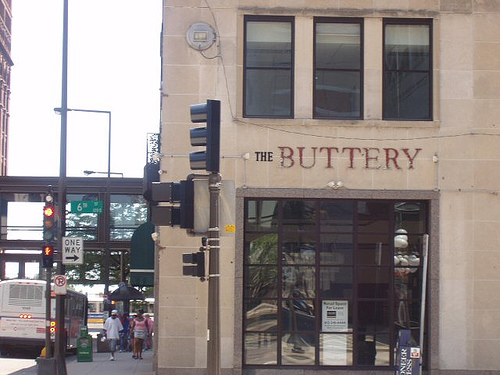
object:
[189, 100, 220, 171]
lamp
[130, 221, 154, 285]
awning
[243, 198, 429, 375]
door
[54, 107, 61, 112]
grey lamps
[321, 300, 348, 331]
paper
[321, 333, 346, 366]
paper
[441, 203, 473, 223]
tan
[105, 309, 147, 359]
couple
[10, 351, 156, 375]
sidewalk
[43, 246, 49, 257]
hand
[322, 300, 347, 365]
papers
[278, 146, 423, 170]
big letters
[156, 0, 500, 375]
building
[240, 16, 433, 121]
brown horses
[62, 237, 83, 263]
sign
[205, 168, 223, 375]
pole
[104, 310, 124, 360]
pedestrian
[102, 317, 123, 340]
white top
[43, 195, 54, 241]
traffic light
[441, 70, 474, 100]
tan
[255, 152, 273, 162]
lettering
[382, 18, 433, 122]
window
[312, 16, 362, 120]
window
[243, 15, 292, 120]
window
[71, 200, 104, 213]
6th street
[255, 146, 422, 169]
buttery